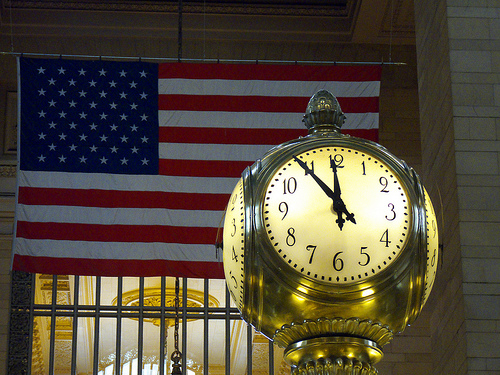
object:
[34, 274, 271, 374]
glass window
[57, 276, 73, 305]
glass window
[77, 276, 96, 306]
glass window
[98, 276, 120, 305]
glass window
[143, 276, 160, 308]
glass window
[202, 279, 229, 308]
window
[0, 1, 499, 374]
building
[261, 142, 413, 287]
clock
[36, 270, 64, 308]
window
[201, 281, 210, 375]
bars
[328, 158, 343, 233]
hands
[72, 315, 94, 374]
window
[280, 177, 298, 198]
number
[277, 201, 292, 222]
number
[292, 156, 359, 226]
minute